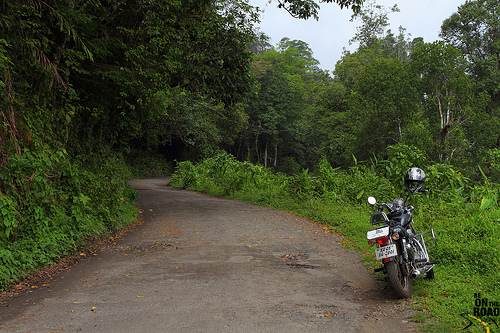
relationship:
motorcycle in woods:
[361, 197, 445, 297] [45, 47, 478, 168]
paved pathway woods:
[122, 229, 323, 324] [45, 47, 478, 168]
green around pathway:
[183, 162, 261, 194] [0, 174, 417, 332]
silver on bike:
[407, 167, 426, 180] [361, 197, 445, 297]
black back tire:
[389, 266, 396, 279] [383, 252, 413, 300]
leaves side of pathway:
[18, 203, 144, 298] [0, 174, 417, 332]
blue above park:
[317, 22, 336, 52] [12, 116, 500, 329]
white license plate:
[375, 249, 389, 260] [374, 244, 398, 260]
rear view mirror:
[369, 212, 414, 297] [367, 195, 377, 207]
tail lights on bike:
[364, 232, 402, 247] [361, 197, 445, 297]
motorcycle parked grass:
[361, 197, 445, 297] [438, 231, 498, 309]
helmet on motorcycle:
[403, 166, 428, 198] [361, 197, 445, 297]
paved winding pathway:
[122, 229, 323, 324] [0, 174, 417, 332]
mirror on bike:
[367, 195, 377, 207] [361, 197, 445, 297]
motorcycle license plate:
[361, 197, 445, 297] [374, 244, 398, 260]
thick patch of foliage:
[67, 135, 168, 167] [28, 67, 117, 225]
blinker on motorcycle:
[390, 231, 402, 244] [361, 197, 445, 297]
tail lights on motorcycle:
[364, 232, 402, 247] [361, 197, 445, 297]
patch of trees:
[242, 125, 395, 162] [45, 47, 478, 168]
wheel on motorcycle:
[383, 252, 413, 300] [361, 197, 445, 297]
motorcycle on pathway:
[361, 197, 445, 297] [0, 174, 417, 332]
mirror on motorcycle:
[367, 195, 377, 207] [361, 197, 445, 297]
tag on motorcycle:
[374, 244, 398, 260] [361, 197, 445, 297]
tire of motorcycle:
[384, 252, 412, 298] [361, 197, 445, 297]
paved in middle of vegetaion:
[122, 229, 323, 324] [225, 117, 340, 208]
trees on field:
[45, 47, 478, 168] [212, 172, 475, 221]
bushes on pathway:
[10, 139, 123, 232] [0, 174, 417, 332]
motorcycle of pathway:
[361, 197, 445, 297] [0, 174, 417, 332]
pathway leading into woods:
[0, 174, 417, 332] [45, 47, 478, 168]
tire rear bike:
[383, 252, 413, 300] [361, 197, 445, 297]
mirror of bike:
[367, 195, 377, 207] [361, 197, 445, 297]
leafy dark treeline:
[134, 49, 242, 106] [197, 65, 496, 181]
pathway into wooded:
[133, 171, 195, 195] [197, 65, 496, 181]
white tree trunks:
[375, 249, 389, 260] [251, 135, 277, 166]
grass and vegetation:
[438, 231, 498, 309] [332, 162, 400, 197]